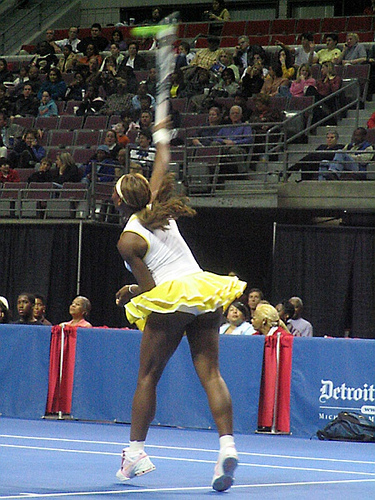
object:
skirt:
[123, 269, 250, 333]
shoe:
[115, 440, 156, 483]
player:
[112, 109, 248, 496]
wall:
[265, 79, 360, 185]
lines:
[1, 475, 375, 499]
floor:
[1, 415, 375, 500]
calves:
[133, 385, 155, 430]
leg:
[130, 309, 187, 441]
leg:
[185, 316, 233, 435]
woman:
[188, 106, 222, 148]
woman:
[273, 62, 318, 97]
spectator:
[249, 301, 287, 336]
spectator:
[219, 297, 256, 336]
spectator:
[285, 296, 313, 339]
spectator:
[59, 295, 93, 328]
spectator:
[6, 291, 43, 326]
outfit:
[119, 203, 247, 333]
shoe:
[212, 434, 238, 492]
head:
[112, 172, 151, 219]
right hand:
[149, 111, 175, 194]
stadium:
[0, 0, 373, 498]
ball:
[130, 25, 169, 38]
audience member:
[322, 126, 374, 180]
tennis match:
[1, 0, 373, 497]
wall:
[220, 97, 262, 112]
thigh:
[139, 303, 185, 349]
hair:
[114, 173, 197, 232]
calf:
[208, 374, 232, 416]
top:
[116, 205, 201, 288]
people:
[304, 60, 340, 105]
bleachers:
[0, 1, 374, 221]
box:
[0, 320, 374, 439]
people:
[334, 33, 367, 66]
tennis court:
[0, 413, 374, 498]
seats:
[0, 13, 373, 215]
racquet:
[146, 13, 184, 126]